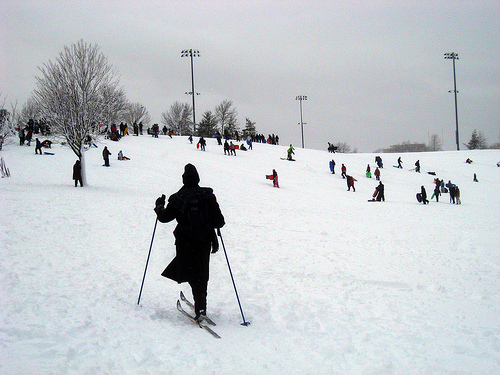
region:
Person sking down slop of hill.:
[274, 136, 309, 171]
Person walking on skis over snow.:
[120, 153, 274, 354]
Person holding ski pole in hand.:
[132, 191, 170, 316]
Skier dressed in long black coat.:
[148, 184, 235, 283]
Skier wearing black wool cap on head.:
[178, 163, 205, 188]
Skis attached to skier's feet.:
[173, 287, 228, 344]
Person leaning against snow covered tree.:
[66, 156, 102, 192]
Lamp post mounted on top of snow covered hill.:
[176, 40, 486, 155]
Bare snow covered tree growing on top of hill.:
[36, 37, 132, 196]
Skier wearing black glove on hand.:
[149, 191, 167, 206]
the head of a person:
[176, 158, 203, 192]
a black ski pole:
[129, 187, 171, 309]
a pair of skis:
[170, 285, 226, 346]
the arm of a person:
[155, 186, 187, 226]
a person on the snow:
[132, 157, 253, 342]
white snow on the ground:
[1, 128, 499, 372]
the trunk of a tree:
[74, 152, 95, 187]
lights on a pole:
[174, 44, 211, 61]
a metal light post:
[187, 52, 203, 135]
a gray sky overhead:
[0, 0, 499, 152]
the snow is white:
[335, 282, 377, 372]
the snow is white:
[320, 269, 362, 349]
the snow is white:
[291, 301, 329, 363]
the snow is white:
[319, 315, 368, 362]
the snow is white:
[301, 280, 366, 365]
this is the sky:
[323, 37, 395, 95]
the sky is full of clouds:
[308, 35, 386, 80]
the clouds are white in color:
[329, 48, 404, 127]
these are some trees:
[41, 58, 305, 180]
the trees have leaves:
[53, 67, 118, 123]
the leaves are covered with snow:
[50, 80, 85, 110]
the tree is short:
[18, 40, 135, 178]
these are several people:
[55, 129, 499, 358]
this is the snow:
[277, 212, 424, 315]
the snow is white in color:
[320, 242, 433, 322]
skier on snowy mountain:
[110, 153, 260, 365]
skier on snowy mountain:
[263, 163, 286, 204]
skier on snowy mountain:
[69, 155, 86, 187]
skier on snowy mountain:
[285, 140, 300, 164]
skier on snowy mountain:
[413, 181, 431, 208]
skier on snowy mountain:
[100, 145, 117, 170]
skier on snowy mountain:
[31, 137, 44, 157]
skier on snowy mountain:
[189, 128, 207, 150]